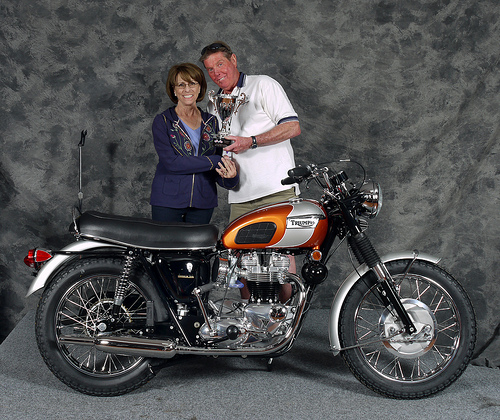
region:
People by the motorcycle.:
[43, 29, 490, 411]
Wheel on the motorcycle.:
[318, 232, 493, 389]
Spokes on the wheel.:
[298, 237, 498, 371]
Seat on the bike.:
[63, 184, 265, 291]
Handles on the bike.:
[268, 139, 388, 258]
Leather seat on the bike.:
[43, 185, 278, 275]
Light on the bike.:
[22, 241, 63, 304]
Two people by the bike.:
[117, 29, 310, 237]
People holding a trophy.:
[161, 39, 302, 207]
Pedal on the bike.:
[168, 282, 303, 374]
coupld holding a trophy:
[141, 26, 281, 177]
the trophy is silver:
[191, 83, 256, 182]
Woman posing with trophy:
[148, 62, 248, 227]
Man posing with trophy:
[199, 40, 301, 302]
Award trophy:
[207, 91, 248, 148]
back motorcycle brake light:
[24, 248, 51, 268]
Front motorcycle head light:
[353, 178, 384, 220]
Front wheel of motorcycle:
[338, 258, 479, 400]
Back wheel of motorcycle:
[36, 255, 171, 397]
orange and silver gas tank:
[221, 197, 330, 250]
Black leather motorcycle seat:
[68, 208, 220, 250]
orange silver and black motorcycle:
[22, 158, 477, 399]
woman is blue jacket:
[158, 118, 207, 194]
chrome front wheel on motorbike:
[363, 286, 436, 371]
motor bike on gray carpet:
[304, 398, 359, 419]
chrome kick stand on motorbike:
[262, 343, 288, 370]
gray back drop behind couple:
[418, 143, 456, 224]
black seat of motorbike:
[108, 218, 143, 246]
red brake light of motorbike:
[19, 244, 61, 279]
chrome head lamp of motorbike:
[362, 167, 382, 220]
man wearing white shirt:
[257, 162, 287, 202]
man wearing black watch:
[245, 135, 287, 167]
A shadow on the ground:
[168, 331, 341, 391]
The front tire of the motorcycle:
[328, 255, 476, 399]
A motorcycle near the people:
[26, 164, 477, 399]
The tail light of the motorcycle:
[23, 243, 45, 265]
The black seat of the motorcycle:
[71, 208, 216, 249]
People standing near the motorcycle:
[152, 43, 302, 223]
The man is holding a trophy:
[206, 88, 244, 148]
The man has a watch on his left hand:
[246, 133, 261, 149]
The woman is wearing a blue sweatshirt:
[151, 111, 221, 208]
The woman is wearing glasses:
[176, 80, 200, 89]